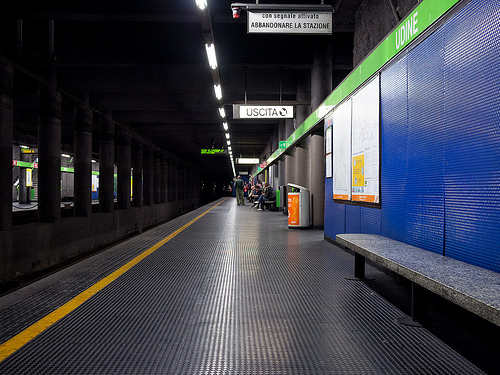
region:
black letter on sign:
[242, 102, 255, 119]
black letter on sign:
[250, 106, 260, 117]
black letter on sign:
[257, 104, 265, 118]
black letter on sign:
[261, 106, 268, 116]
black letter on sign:
[263, 106, 271, 118]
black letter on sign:
[269, 106, 281, 120]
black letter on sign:
[249, 20, 256, 30]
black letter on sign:
[253, 18, 260, 32]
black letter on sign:
[260, 18, 268, 30]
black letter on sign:
[291, 21, 299, 31]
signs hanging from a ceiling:
[231, 15, 322, 137]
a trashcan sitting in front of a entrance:
[283, 171, 321, 242]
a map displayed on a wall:
[326, 87, 414, 247]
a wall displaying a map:
[324, 96, 401, 221]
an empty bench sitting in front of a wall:
[326, 219, 499, 361]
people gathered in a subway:
[223, 164, 275, 215]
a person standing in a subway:
[226, 164, 256, 218]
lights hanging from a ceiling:
[193, 25, 232, 120]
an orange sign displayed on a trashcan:
[281, 194, 306, 248]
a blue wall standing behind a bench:
[412, 104, 487, 285]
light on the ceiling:
[187, 0, 219, 18]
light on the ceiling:
[195, 26, 225, 74]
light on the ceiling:
[206, 76, 233, 111]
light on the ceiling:
[212, 98, 229, 125]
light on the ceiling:
[219, 118, 230, 132]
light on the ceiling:
[217, 128, 232, 148]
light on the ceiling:
[227, 148, 237, 165]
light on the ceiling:
[230, 159, 244, 174]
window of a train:
[12, 119, 39, 204]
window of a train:
[53, 146, 83, 204]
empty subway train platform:
[11, 170, 228, 370]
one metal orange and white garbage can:
[284, 181, 311, 231]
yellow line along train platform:
[12, 195, 230, 360]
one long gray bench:
[335, 218, 499, 332]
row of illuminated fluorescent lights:
[193, 3, 238, 183]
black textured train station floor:
[171, 236, 286, 374]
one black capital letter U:
[246, 104, 253, 116]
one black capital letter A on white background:
[271, 107, 277, 117]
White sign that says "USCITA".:
[238, 105, 293, 115]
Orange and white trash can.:
[286, 183, 309, 229]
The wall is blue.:
[325, 0, 494, 274]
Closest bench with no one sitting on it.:
[334, 232, 499, 327]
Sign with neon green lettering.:
[201, 148, 228, 155]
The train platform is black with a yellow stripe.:
[2, 196, 498, 373]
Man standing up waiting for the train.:
[234, 174, 244, 204]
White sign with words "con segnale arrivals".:
[247, 10, 328, 28]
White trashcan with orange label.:
[285, 180, 307, 225]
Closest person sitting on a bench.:
[259, 182, 275, 210]